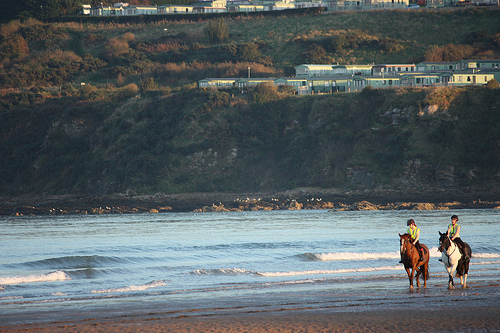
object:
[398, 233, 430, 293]
horse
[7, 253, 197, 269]
wave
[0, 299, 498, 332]
beach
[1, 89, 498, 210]
hill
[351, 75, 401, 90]
building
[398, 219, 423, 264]
lady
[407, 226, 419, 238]
shirt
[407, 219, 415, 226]
helmet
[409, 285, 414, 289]
hoove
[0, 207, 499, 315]
ocean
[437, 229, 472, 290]
horse